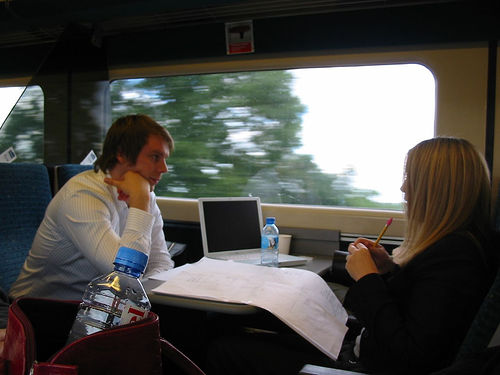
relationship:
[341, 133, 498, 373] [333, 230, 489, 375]
woman wearing shirt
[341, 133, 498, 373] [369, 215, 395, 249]
woman holding pencil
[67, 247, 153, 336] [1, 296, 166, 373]
water bottle in bag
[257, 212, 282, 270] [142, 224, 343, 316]
water bottle on table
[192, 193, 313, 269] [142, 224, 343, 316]
laptop on table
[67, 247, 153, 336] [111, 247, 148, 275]
water bottle with cap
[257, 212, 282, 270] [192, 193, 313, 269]
water bottle near laptop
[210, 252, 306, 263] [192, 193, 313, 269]
keyboard on laptop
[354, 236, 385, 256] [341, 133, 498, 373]
right hand of woman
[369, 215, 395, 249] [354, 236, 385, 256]
pencil in right hand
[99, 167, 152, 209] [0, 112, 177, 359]
right hand of man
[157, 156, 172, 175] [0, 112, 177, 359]
nose of man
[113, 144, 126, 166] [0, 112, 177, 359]
ear of man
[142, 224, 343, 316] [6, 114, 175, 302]
table between man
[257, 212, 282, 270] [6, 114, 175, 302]
water bottle between man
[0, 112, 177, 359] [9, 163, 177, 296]
man wearing shirt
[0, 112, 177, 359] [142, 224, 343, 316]
man sitting at table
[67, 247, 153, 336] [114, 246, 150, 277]
water bottle has top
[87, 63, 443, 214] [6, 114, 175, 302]
window beside man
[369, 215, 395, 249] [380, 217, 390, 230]
pencil has eraser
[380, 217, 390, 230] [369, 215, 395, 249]
eraser on pencil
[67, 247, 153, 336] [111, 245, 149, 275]
water bottle has cap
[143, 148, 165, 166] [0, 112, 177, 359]
eye of man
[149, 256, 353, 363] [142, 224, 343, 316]
paper on table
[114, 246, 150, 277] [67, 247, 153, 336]
top on water bottle